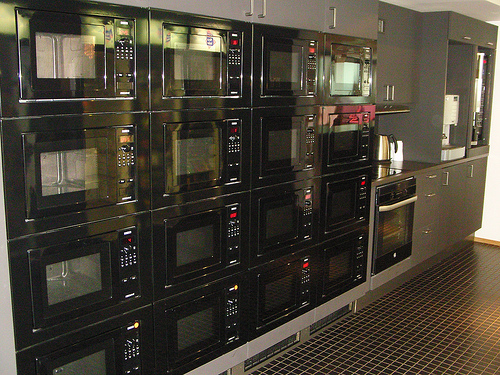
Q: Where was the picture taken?
A: In a kitchen.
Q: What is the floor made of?
A: Tile.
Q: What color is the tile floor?
A: Black.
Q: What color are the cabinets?
A: Gray.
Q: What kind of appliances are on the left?
A: Microwaves.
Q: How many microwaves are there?
A: Sixteen.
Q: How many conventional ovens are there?
A: One.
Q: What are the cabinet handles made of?
A: Metal.